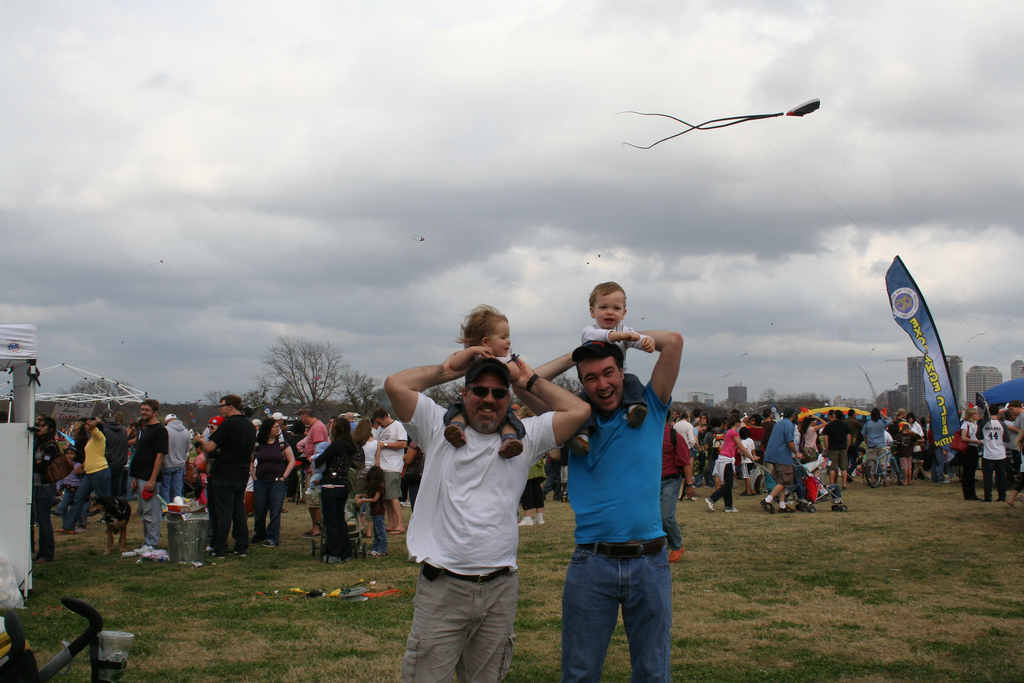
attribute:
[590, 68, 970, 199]
kite — aired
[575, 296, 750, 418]
toddler — pictured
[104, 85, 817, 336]
sky — cloudy looking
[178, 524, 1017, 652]
grass — yellow, green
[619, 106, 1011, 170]
kite — black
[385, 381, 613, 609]
shirt — white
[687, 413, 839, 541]
shirt — pink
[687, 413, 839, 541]
pants — black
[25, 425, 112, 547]
woman — young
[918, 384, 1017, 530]
bag — red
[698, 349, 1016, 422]
buildings — distant